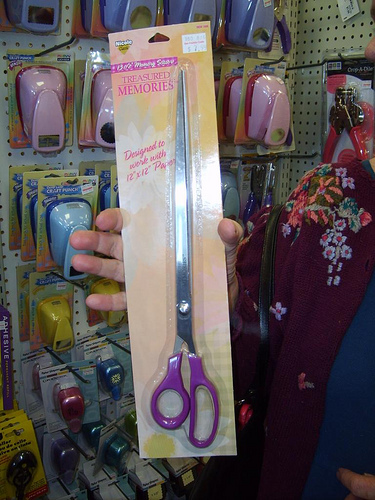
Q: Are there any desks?
A: No, there are no desks.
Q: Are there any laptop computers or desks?
A: No, there are no desks or laptop computers.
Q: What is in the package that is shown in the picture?
A: The scissors are in the package.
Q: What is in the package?
A: The scissors are in the package.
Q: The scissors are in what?
A: The scissors are in the package.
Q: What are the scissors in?
A: The scissors are in the package.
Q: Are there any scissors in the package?
A: Yes, there are scissors in the package.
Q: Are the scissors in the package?
A: Yes, the scissors are in the package.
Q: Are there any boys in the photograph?
A: No, there are no boys.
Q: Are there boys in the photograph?
A: No, there are no boys.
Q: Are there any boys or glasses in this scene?
A: No, there are no boys or glasses.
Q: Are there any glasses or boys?
A: No, there are no boys or glasses.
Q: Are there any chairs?
A: No, there are no chairs.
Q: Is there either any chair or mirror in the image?
A: No, there are no chairs or mirrors.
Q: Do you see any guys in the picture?
A: No, there are no guys.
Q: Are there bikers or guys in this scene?
A: No, there are no guys or bikers.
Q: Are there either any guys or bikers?
A: No, there are no guys or bikers.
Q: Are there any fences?
A: No, there are no fences.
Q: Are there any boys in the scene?
A: No, there are no boys.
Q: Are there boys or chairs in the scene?
A: No, there are no boys or chairs.